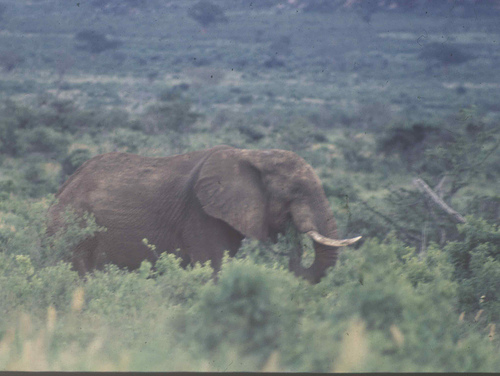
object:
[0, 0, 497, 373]
brush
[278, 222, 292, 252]
leaves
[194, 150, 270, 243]
ear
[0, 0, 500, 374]
plain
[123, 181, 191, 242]
wrinkles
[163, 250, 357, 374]
shrubbery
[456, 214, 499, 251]
shrubbery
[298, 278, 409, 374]
shrubbery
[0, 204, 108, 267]
shrubbery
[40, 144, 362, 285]
elephant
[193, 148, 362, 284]
head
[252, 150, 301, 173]
mud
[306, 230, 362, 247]
tusk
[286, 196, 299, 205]
eye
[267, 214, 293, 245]
mouth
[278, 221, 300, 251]
food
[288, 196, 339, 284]
trunk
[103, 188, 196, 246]
skin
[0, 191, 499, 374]
plant life